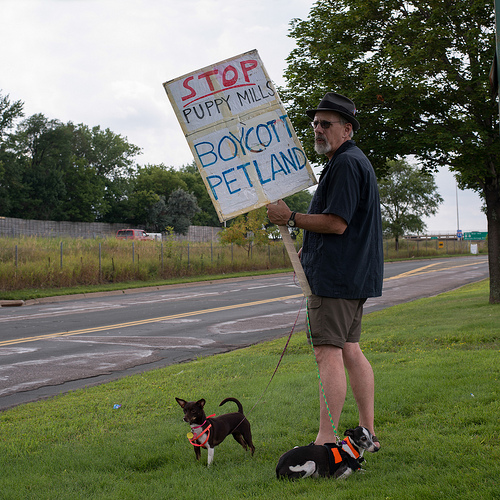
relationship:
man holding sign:
[266, 94, 382, 448] [162, 48, 319, 224]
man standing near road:
[266, 94, 382, 448] [1, 254, 496, 407]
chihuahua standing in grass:
[175, 397, 256, 469] [4, 276, 497, 498]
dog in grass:
[276, 427, 380, 486] [4, 276, 497, 498]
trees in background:
[0, 92, 314, 219] [0, 93, 485, 228]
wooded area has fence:
[0, 92, 314, 219] [1, 218, 262, 245]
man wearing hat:
[266, 94, 382, 448] [305, 93, 362, 129]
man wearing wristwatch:
[266, 94, 382, 448] [288, 211, 296, 227]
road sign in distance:
[466, 231, 487, 243] [403, 154, 487, 247]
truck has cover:
[117, 230, 156, 243] [113, 234, 132, 237]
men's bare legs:
[266, 94, 382, 448] [316, 342, 376, 439]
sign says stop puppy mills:
[162, 48, 319, 224] [180, 59, 278, 123]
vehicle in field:
[117, 230, 156, 243] [3, 238, 438, 291]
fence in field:
[1, 218, 262, 245] [3, 238, 438, 291]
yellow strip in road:
[0, 255, 486, 355] [1, 254, 496, 407]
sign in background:
[466, 231, 487, 243] [434, 170, 489, 254]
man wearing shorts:
[266, 94, 382, 448] [308, 291, 367, 348]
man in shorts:
[266, 94, 382, 448] [308, 291, 367, 348]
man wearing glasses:
[266, 94, 382, 448] [311, 120, 334, 132]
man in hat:
[266, 94, 382, 448] [305, 93, 362, 129]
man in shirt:
[266, 94, 382, 448] [300, 141, 385, 298]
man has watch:
[266, 94, 382, 448] [288, 211, 296, 227]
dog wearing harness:
[276, 427, 380, 486] [325, 437, 363, 471]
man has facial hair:
[266, 94, 382, 448] [313, 133, 331, 156]